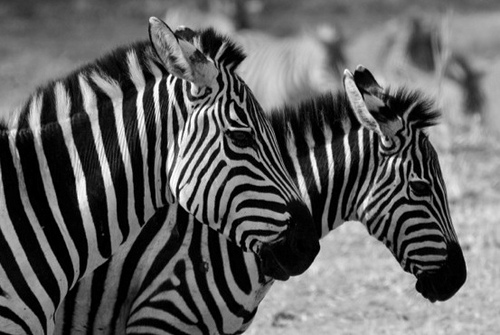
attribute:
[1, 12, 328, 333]
zebra — black, small, smaller, standing, facing, white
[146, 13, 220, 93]
ear — wide, large, white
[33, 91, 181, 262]
neck — black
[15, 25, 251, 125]
mane — soft, black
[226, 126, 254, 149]
eye — black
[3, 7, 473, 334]
zebras — white, black, staring, blurry, standing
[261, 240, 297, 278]
mouth — black, dark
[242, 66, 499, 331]
grass — light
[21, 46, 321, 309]
zebra — bigger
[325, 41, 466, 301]
zebra — black